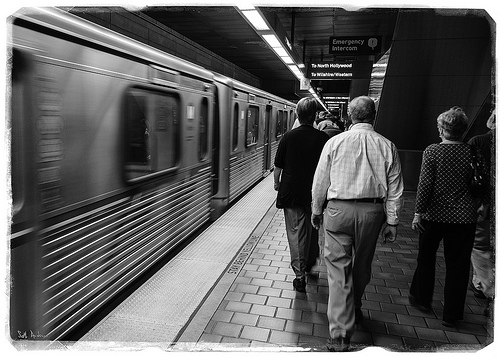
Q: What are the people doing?
A: Walking.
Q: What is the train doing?
A: Passing.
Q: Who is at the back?
A: Man in plaid shirt.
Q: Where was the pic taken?
A: In a train station.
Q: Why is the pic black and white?
A: Camera settings were like that.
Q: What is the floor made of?
A: Bricks.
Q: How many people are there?
A: 4.